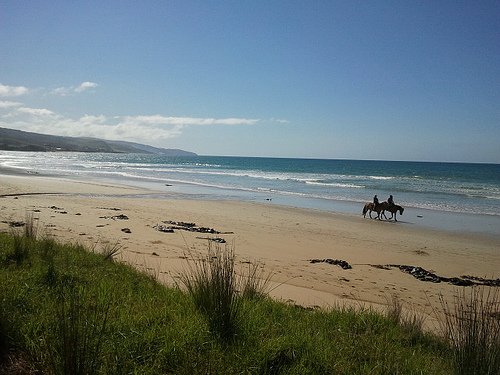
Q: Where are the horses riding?
A: Beach.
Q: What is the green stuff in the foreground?
A: Grass.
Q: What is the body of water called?
A: Ocean.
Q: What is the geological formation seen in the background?
A: Mountains.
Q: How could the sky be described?
A: Clear.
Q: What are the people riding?
A: Horses.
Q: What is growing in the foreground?
A: Grass.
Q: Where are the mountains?
A: Background.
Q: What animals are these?
A: Horses.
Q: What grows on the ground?
A: Grass.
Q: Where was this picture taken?
A: The beach.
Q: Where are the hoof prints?
A: In the sand.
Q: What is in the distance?
A: A mountain.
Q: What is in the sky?
A: Clouds.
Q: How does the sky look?
A: Clear.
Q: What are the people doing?
A: Riding horses.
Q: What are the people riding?
A: Horses.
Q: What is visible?
A: The horse.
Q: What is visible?
A: The horse.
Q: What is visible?
A: The horse.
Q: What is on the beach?
A: The sea weed.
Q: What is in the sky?
A: White clouds.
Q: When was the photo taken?
A: Daytime.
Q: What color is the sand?
A: Brown.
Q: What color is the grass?
A: Green.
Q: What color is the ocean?
A: Blue.